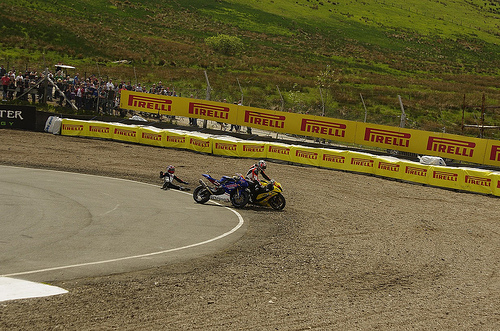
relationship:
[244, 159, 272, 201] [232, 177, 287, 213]
man on motorcycle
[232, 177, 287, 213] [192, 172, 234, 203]
motorcycle collided with motorcycle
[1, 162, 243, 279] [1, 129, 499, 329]
line on racetrack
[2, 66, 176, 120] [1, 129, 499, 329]
people at racetrack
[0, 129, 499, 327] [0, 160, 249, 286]
dirt next to racetrack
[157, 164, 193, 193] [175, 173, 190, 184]
man has arm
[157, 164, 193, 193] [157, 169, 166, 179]
man has arm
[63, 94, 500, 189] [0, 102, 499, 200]
sign on wall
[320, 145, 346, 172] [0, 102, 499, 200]
sign on wall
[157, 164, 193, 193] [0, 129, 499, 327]
man on dirt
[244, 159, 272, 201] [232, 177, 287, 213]
man riding motorcycle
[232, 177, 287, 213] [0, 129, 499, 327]
motorcycle on dirt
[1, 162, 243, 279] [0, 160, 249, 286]
line edge of racetrack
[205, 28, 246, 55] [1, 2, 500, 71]
bush on hillside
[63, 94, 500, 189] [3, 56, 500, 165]
sign on fence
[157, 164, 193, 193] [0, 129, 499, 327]
rider on dirt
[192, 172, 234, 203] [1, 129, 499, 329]
motorcycle on racetrack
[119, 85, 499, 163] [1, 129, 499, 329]
banner side of racetrack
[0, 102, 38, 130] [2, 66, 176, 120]
banner front of people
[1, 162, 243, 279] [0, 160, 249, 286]
line around racetrack